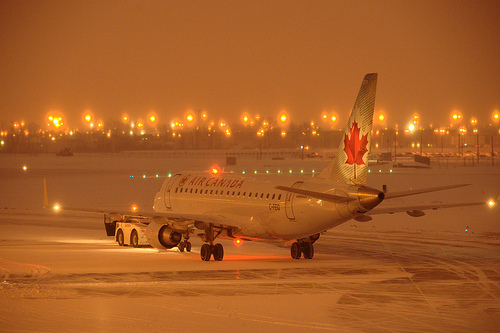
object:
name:
[188, 176, 245, 188]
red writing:
[188, 176, 245, 189]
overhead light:
[211, 133, 496, 243]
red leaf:
[343, 118, 370, 179]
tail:
[317, 72, 378, 184]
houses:
[121, 110, 243, 144]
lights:
[0, 100, 499, 142]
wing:
[367, 183, 487, 216]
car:
[104, 211, 167, 248]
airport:
[0, 104, 500, 333]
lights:
[131, 168, 393, 178]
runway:
[0, 160, 499, 333]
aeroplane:
[144, 72, 484, 261]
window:
[175, 186, 283, 200]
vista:
[5, 106, 495, 164]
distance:
[0, 99, 499, 169]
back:
[274, 72, 487, 261]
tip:
[358, 183, 386, 210]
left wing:
[363, 200, 492, 214]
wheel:
[290, 241, 315, 260]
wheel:
[200, 243, 225, 261]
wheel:
[179, 240, 191, 252]